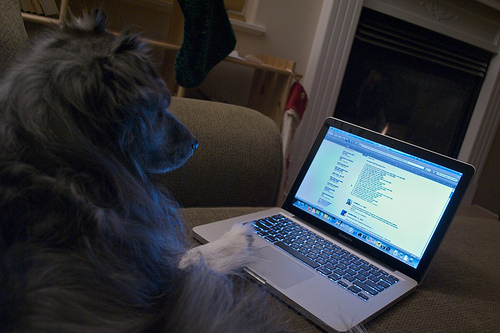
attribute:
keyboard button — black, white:
[362, 260, 372, 273]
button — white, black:
[278, 218, 288, 224]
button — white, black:
[276, 212, 287, 218]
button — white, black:
[283, 217, 292, 224]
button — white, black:
[270, 214, 279, 221]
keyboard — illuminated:
[236, 203, 406, 305]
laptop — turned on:
[198, 100, 469, 324]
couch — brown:
[182, 86, 306, 227]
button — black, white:
[347, 284, 361, 296]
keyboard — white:
[243, 213, 399, 300]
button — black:
[262, 233, 278, 243]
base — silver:
[194, 194, 420, 328]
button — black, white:
[316, 246, 331, 260]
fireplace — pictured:
[316, 6, 488, 220]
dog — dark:
[4, 13, 291, 323]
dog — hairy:
[83, 36, 140, 84]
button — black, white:
[293, 233, 300, 238]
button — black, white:
[348, 281, 358, 293]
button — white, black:
[354, 277, 383, 295]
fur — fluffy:
[44, 123, 156, 294]